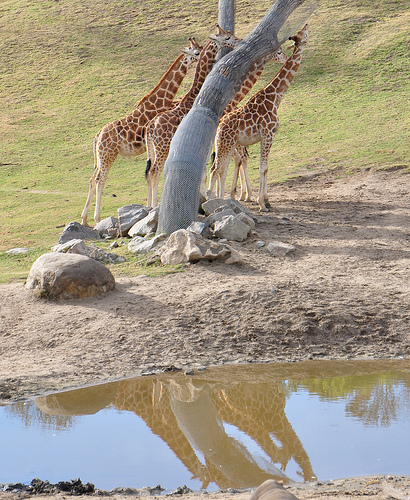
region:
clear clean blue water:
[68, 456, 141, 477]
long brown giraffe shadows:
[231, 389, 327, 464]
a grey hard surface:
[50, 340, 176, 365]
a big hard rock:
[35, 262, 117, 298]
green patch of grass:
[17, 177, 53, 227]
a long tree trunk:
[163, 135, 215, 225]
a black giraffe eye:
[192, 51, 201, 55]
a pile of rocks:
[165, 200, 255, 264]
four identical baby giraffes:
[95, 90, 281, 187]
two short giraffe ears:
[188, 33, 204, 50]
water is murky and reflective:
[21, 357, 399, 484]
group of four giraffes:
[77, 23, 327, 242]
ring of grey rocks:
[29, 206, 290, 300]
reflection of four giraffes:
[66, 369, 350, 484]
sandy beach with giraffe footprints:
[164, 291, 361, 370]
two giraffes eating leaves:
[77, 30, 238, 246]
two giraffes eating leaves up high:
[255, 24, 340, 79]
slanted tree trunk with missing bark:
[175, 8, 259, 228]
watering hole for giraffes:
[8, 387, 364, 480]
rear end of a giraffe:
[76, 124, 126, 188]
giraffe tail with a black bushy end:
[138, 115, 164, 186]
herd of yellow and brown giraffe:
[86, 21, 327, 246]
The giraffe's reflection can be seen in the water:
[16, 338, 387, 499]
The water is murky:
[21, 345, 381, 497]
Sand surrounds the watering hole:
[26, 246, 387, 369]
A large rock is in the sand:
[30, 237, 174, 346]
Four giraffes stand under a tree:
[99, 38, 331, 227]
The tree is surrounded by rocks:
[82, 151, 284, 272]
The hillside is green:
[35, 10, 386, 226]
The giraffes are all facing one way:
[76, 30, 346, 213]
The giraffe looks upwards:
[198, 16, 328, 211]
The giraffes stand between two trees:
[70, 4, 315, 224]